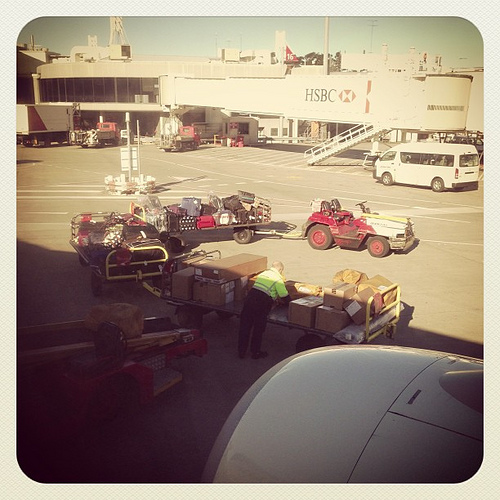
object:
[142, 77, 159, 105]
window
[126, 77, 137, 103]
window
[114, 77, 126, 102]
window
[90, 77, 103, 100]
window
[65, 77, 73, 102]
window